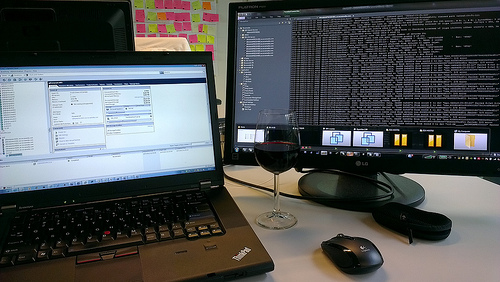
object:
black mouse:
[321, 233, 384, 275]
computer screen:
[220, 0, 500, 177]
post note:
[183, 21, 192, 31]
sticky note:
[147, 11, 159, 22]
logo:
[355, 160, 369, 167]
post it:
[147, 11, 157, 21]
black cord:
[219, 170, 307, 200]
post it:
[135, 9, 146, 23]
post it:
[146, 11, 157, 21]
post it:
[157, 11, 167, 20]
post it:
[175, 8, 184, 22]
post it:
[183, 11, 189, 21]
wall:
[133, 0, 228, 61]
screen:
[0, 50, 226, 216]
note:
[202, 0, 212, 10]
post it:
[135, 10, 145, 20]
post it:
[136, 23, 146, 33]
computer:
[0, 49, 275, 282]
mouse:
[319, 233, 383, 276]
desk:
[220, 157, 500, 282]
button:
[171, 222, 182, 230]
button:
[197, 224, 211, 237]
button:
[115, 230, 130, 239]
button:
[145, 227, 156, 235]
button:
[136, 206, 146, 218]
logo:
[359, 245, 371, 253]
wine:
[251, 139, 298, 173]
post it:
[156, 10, 177, 22]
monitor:
[0, 51, 224, 214]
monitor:
[226, 0, 499, 173]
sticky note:
[202, 3, 211, 11]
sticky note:
[136, 9, 145, 22]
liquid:
[254, 142, 300, 175]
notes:
[128, 2, 228, 46]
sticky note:
[206, 35, 215, 45]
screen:
[221, 0, 500, 212]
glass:
[254, 107, 301, 229]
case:
[371, 202, 453, 245]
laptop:
[0, 51, 276, 280]